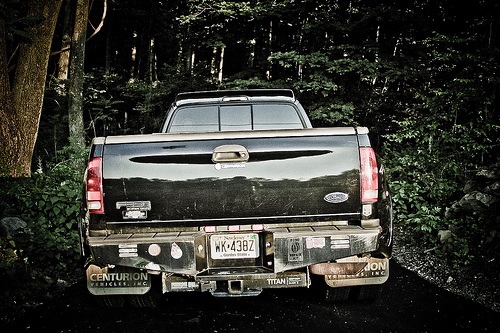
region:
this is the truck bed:
[56, 108, 387, 296]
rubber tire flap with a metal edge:
[82, 260, 152, 300]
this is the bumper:
[75, 225, 375, 280]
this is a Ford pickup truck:
[75, 65, 395, 300]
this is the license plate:
[205, 227, 275, 267]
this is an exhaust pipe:
[306, 256, 371, 276]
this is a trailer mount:
[225, 277, 245, 292]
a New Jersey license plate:
[206, 230, 259, 256]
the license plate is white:
[205, 226, 260, 261]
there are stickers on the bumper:
[72, 222, 392, 281]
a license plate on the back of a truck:
[207, 236, 262, 258]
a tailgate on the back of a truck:
[100, 127, 365, 225]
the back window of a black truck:
[167, 98, 308, 131]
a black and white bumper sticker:
[85, 266, 152, 293]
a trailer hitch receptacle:
[224, 278, 245, 295]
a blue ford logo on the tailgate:
[320, 189, 350, 205]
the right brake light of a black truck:
[356, 142, 378, 205]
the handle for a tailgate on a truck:
[206, 140, 253, 166]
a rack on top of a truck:
[166, 83, 298, 102]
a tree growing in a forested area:
[61, 3, 88, 153]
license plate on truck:
[214, 234, 255, 259]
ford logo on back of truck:
[323, 187, 348, 204]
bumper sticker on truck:
[89, 262, 147, 286]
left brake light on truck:
[87, 158, 107, 217]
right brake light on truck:
[357, 141, 381, 207]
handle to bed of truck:
[208, 144, 250, 163]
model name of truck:
[116, 197, 151, 211]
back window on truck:
[178, 108, 302, 129]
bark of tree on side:
[0, 0, 55, 177]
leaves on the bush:
[4, 177, 79, 260]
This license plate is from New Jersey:
[215, 215, 266, 279]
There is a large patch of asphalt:
[298, 310, 305, 325]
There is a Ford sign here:
[327, 188, 352, 217]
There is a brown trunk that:
[1, 98, 26, 161]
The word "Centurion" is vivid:
[91, 270, 138, 310]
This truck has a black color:
[276, 193, 278, 203]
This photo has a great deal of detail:
[160, 94, 229, 254]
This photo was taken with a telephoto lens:
[127, 125, 219, 315]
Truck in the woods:
[55, 95, 382, 283]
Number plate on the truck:
[198, 232, 266, 271]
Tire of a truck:
[102, 293, 180, 316]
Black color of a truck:
[133, 126, 307, 205]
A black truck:
[103, 83, 392, 283]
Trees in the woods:
[407, 75, 479, 195]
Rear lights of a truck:
[79, 148, 383, 213]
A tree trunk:
[14, 22, 48, 126]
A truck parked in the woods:
[98, 91, 373, 256]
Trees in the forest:
[394, 73, 489, 224]